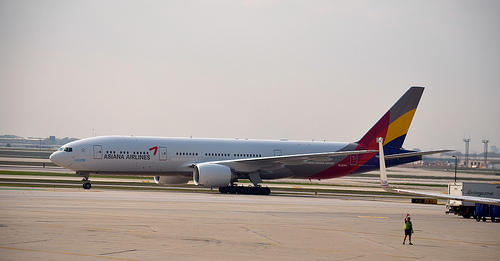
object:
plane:
[48, 86, 456, 196]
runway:
[0, 148, 500, 260]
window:
[120, 151, 123, 154]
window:
[106, 151, 109, 153]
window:
[110, 151, 112, 153]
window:
[113, 151, 114, 153]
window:
[124, 151, 126, 153]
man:
[402, 213, 415, 245]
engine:
[193, 163, 241, 187]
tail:
[356, 85, 427, 152]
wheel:
[82, 180, 94, 190]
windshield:
[58, 147, 73, 152]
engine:
[154, 176, 193, 185]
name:
[103, 152, 151, 160]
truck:
[448, 182, 500, 219]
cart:
[474, 202, 500, 223]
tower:
[464, 134, 472, 165]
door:
[93, 144, 102, 159]